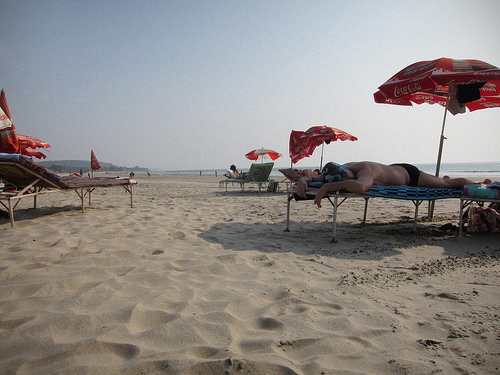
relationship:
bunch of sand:
[8, 224, 497, 368] [17, 225, 499, 364]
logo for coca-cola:
[390, 78, 429, 97] [390, 84, 432, 92]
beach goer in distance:
[143, 170, 153, 177] [69, 162, 223, 181]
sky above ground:
[1, 1, 496, 159] [0, 171, 499, 373]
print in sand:
[137, 306, 175, 330] [17, 225, 499, 364]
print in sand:
[110, 264, 135, 278] [17, 225, 499, 364]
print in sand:
[256, 316, 287, 330] [17, 225, 499, 364]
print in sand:
[174, 258, 209, 265] [17, 225, 499, 364]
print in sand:
[174, 272, 208, 287] [17, 225, 499, 364]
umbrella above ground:
[383, 49, 494, 176] [368, 212, 496, 311]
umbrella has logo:
[383, 49, 494, 176] [390, 78, 429, 97]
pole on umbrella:
[434, 95, 449, 182] [383, 49, 494, 176]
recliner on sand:
[220, 166, 270, 186] [17, 225, 499, 364]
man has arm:
[295, 161, 493, 208] [316, 178, 374, 197]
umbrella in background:
[86, 152, 107, 169] [51, 164, 219, 187]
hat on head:
[314, 161, 349, 184] [323, 162, 359, 193]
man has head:
[301, 160, 492, 207] [323, 162, 359, 193]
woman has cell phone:
[293, 164, 321, 175] [298, 166, 304, 172]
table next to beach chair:
[454, 177, 495, 223] [293, 168, 495, 206]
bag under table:
[462, 205, 498, 233] [454, 177, 495, 223]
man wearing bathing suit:
[301, 160, 492, 207] [392, 158, 426, 187]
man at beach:
[301, 160, 492, 207] [0, 171, 499, 373]